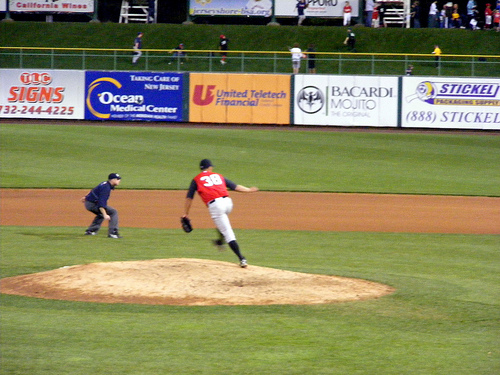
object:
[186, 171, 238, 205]
jersey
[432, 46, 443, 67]
man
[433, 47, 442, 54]
jacket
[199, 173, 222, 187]
38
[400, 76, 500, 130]
sign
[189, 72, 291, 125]
sign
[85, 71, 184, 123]
sign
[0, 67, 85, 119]
sign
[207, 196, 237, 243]
pants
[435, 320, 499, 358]
grass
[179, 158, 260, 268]
baseball player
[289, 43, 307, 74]
people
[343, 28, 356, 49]
people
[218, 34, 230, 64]
people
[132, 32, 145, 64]
people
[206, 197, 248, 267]
legs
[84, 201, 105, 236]
legs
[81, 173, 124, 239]
player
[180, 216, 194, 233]
catcher glove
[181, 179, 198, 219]
hand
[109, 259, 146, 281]
base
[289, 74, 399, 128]
poster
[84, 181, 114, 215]
shirt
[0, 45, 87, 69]
fence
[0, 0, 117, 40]
background